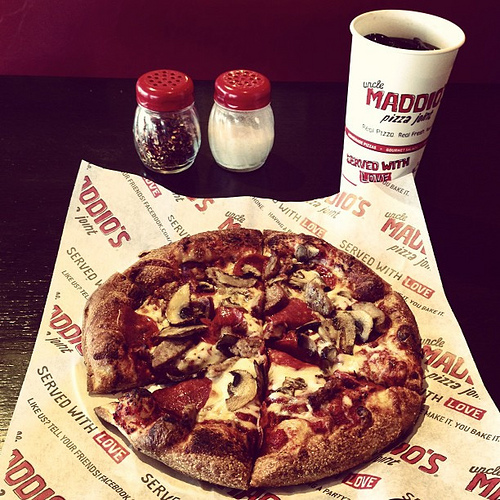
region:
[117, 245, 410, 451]
Pepperoni on a pizza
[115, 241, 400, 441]
Pepperoni is on a pizza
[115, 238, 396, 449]
Slices of pepperoni on a pizza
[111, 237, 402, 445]
Slices of pepperoni are on a pizza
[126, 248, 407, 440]
Mushrooms on a pizza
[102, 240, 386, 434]
Mushrooms are on a pizza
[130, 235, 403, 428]
Sliced mushrooms on a pizza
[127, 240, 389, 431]
Sliced mushrooms are on a pizza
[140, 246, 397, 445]
Melted cheese on a pizza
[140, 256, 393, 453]
Melted cheese is on pizza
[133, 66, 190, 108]
red cap on bottle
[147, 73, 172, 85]
small holes in red cap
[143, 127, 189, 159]
red pepper flakes in jar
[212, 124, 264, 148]
grainy white salt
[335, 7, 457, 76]
top of white paper cup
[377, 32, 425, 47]
brown liquid in cup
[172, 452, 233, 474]
brown crust on pizza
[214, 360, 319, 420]
slices of brown mushroom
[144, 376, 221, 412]
round pieces of pepperoni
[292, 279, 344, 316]
small bits on brown sausage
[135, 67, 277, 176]
Two glass shakers on table.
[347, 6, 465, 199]
Paper cup on table.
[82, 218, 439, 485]
Small pizza on paper.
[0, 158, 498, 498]
White paper with red and black letters.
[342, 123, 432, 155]
Red band with white letters on cup.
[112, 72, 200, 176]
Shaker filled with crushed red pepper.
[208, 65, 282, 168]
Shaker filled with grated cheese.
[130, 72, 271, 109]
Red tops on glass shakers.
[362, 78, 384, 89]
The word 'uncle' on cup.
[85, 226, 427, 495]
Pizza cut into six slices.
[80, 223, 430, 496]
the pizza is brown in shape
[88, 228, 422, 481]
the pizza is sliced in pieces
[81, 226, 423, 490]
the pizza has a crust at the edge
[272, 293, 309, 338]
pepperoni is on the pizza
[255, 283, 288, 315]
mushrooms is on the pizza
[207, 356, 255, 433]
the cheese is white in color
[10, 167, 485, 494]
the pizza is on a paper wrapping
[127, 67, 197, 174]
a bottle container is on the table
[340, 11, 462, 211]
a paper cup is on the table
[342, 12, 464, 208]
the paper cup is white in color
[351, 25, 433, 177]
cup with liquid in it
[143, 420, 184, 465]
crust of pizza is burnt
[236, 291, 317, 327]
pepperoni on top of pizza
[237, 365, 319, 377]
melted cheese on pizza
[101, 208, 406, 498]
pizza on paper wrap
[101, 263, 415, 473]
six slices of pizza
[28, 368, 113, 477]
paper with writing on it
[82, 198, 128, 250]
red lettering on paper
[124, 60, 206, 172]
red pepper in shaker